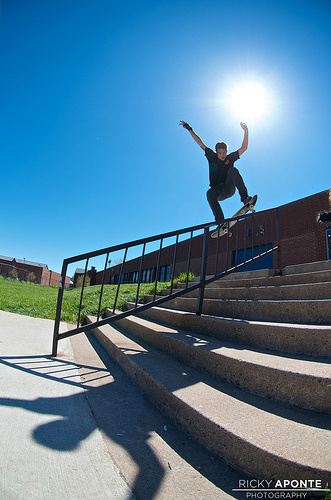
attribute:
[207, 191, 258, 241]
skateboard — in the air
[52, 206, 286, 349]
handrail — metal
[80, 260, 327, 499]
stairs — cement, concrete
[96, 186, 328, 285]
building — red, large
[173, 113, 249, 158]
arms — outstretched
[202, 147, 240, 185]
shirt — black, dark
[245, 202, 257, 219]
wheels — yellow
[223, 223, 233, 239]
wheels — yellow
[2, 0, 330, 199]
sky — blue, clear, blue colored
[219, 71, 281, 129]
sun — bright, shining, white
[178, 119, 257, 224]
skater — jumping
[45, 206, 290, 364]
rail — black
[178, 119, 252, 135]
hands — up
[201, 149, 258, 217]
clothes — black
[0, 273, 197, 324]
grass — on a hill, green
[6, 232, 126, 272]
clouds — white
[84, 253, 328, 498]
steps — light brown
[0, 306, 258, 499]
sidewalk — grey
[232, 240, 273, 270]
door — blue, large